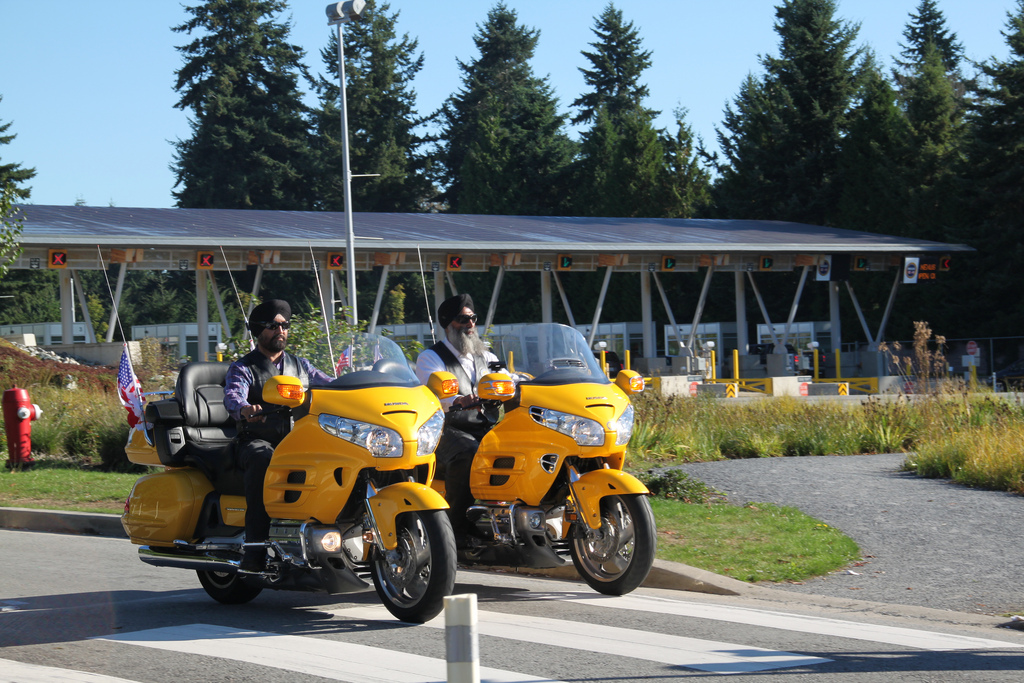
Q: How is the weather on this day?
A: It is clear.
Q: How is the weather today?
A: It is clear.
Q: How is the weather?
A: It is clear.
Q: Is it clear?
A: Yes, it is clear.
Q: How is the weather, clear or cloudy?
A: It is clear.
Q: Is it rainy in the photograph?
A: No, it is clear.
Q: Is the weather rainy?
A: No, it is clear.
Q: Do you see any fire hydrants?
A: Yes, there is a fire hydrant.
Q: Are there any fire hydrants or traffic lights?
A: Yes, there is a fire hydrant.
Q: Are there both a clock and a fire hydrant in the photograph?
A: No, there is a fire hydrant but no clocks.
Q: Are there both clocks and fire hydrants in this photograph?
A: No, there is a fire hydrant but no clocks.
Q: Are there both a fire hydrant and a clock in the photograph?
A: No, there is a fire hydrant but no clocks.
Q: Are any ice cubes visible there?
A: No, there are no ice cubes.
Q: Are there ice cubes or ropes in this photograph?
A: No, there are no ice cubes or ropes.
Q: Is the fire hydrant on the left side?
A: Yes, the fire hydrant is on the left of the image.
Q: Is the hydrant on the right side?
A: No, the hydrant is on the left of the image.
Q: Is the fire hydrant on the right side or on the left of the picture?
A: The fire hydrant is on the left of the image.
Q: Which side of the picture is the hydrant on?
A: The hydrant is on the left of the image.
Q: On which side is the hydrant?
A: The hydrant is on the left of the image.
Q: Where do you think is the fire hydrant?
A: The fire hydrant is on the grass.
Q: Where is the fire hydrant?
A: The fire hydrant is on the grass.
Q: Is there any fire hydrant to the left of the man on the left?
A: Yes, there is a fire hydrant to the left of the man.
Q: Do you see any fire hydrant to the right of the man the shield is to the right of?
A: No, the fire hydrant is to the left of the man.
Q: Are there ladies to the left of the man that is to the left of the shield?
A: No, there is a fire hydrant to the left of the man.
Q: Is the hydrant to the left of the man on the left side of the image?
A: Yes, the hydrant is to the left of the man.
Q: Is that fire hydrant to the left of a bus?
A: No, the fire hydrant is to the left of the man.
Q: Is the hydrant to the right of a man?
A: No, the hydrant is to the left of a man.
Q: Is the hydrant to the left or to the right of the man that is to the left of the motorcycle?
A: The hydrant is to the left of the man.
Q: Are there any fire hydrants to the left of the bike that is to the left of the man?
A: Yes, there is a fire hydrant to the left of the bike.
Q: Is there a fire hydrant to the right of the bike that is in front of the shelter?
A: No, the fire hydrant is to the left of the bike.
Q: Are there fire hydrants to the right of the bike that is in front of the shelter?
A: No, the fire hydrant is to the left of the bike.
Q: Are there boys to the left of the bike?
A: No, there is a fire hydrant to the left of the bike.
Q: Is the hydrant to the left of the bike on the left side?
A: Yes, the hydrant is to the left of the bike.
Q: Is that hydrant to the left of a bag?
A: No, the hydrant is to the left of the bike.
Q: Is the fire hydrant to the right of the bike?
A: No, the fire hydrant is to the left of the bike.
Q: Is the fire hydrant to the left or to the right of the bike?
A: The fire hydrant is to the left of the bike.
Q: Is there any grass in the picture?
A: Yes, there is grass.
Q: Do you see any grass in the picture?
A: Yes, there is grass.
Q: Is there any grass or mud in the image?
A: Yes, there is grass.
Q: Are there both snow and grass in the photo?
A: No, there is grass but no snow.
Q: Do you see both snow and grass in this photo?
A: No, there is grass but no snow.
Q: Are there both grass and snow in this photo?
A: No, there is grass but no snow.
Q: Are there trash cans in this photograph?
A: No, there are no trash cans.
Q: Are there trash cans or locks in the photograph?
A: No, there are no trash cans or locks.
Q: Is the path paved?
A: Yes, the path is paved.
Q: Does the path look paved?
A: Yes, the path is paved.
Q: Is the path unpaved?
A: No, the path is paved.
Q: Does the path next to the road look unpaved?
A: No, the path is paved.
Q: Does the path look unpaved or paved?
A: The path is paved.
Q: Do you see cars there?
A: No, there are no cars.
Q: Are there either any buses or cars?
A: No, there are no cars or buses.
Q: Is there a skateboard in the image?
A: No, there are no skateboards.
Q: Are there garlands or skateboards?
A: No, there are no skateboards or garlands.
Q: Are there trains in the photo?
A: No, there are no trains.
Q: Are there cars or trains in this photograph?
A: No, there are no trains or cars.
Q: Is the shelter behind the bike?
A: Yes, the shelter is behind the bike.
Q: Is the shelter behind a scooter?
A: No, the shelter is behind the bike.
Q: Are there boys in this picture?
A: No, there are no boys.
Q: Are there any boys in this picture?
A: No, there are no boys.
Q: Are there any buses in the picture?
A: No, there are no buses.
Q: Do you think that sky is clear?
A: Yes, the sky is clear.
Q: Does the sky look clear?
A: Yes, the sky is clear.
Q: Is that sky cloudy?
A: No, the sky is clear.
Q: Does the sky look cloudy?
A: No, the sky is clear.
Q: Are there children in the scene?
A: No, there are no children.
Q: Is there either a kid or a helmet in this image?
A: No, there are no children or helmets.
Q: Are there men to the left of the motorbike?
A: Yes, there is a man to the left of the motorbike.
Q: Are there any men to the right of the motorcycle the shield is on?
A: No, the man is to the left of the motorcycle.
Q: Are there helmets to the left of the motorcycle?
A: No, there is a man to the left of the motorcycle.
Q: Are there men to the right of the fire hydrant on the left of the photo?
A: Yes, there is a man to the right of the hydrant.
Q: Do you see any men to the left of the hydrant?
A: No, the man is to the right of the hydrant.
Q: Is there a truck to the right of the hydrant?
A: No, there is a man to the right of the hydrant.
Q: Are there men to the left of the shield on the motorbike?
A: Yes, there is a man to the left of the shield.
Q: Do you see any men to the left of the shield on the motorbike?
A: Yes, there is a man to the left of the shield.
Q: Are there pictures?
A: No, there are no pictures.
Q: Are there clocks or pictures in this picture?
A: No, there are no pictures or clocks.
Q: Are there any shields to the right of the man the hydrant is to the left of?
A: Yes, there is a shield to the right of the man.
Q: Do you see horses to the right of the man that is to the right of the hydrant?
A: No, there is a shield to the right of the man.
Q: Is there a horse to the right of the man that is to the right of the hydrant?
A: No, there is a shield to the right of the man.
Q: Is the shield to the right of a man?
A: Yes, the shield is to the right of a man.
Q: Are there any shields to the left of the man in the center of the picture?
A: Yes, there is a shield to the left of the man.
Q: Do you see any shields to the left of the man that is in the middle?
A: Yes, there is a shield to the left of the man.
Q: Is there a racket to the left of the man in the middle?
A: No, there is a shield to the left of the man.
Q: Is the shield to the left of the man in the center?
A: Yes, the shield is to the left of the man.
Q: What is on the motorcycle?
A: The shield is on the motorcycle.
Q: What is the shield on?
A: The shield is on the motorbike.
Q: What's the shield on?
A: The shield is on the motorbike.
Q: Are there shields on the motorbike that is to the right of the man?
A: Yes, there is a shield on the motorcycle.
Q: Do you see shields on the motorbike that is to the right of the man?
A: Yes, there is a shield on the motorcycle.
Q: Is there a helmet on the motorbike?
A: No, there is a shield on the motorbike.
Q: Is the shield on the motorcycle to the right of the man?
A: Yes, the shield is on the motorcycle.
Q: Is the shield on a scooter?
A: No, the shield is on the motorcycle.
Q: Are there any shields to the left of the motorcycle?
A: Yes, there is a shield to the left of the motorcycle.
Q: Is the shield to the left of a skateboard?
A: No, the shield is to the left of the motorcycle.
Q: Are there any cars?
A: No, there are no cars.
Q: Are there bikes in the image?
A: Yes, there is a bike.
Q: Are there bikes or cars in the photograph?
A: Yes, there is a bike.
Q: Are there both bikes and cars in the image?
A: No, there is a bike but no cars.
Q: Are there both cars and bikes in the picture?
A: No, there is a bike but no cars.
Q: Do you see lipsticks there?
A: No, there are no lipsticks.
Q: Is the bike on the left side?
A: Yes, the bike is on the left of the image.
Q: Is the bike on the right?
A: No, the bike is on the left of the image.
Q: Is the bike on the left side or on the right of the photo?
A: The bike is on the left of the image.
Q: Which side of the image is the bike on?
A: The bike is on the left of the image.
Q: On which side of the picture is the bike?
A: The bike is on the left of the image.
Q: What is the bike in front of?
A: The bike is in front of the shelter.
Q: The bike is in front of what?
A: The bike is in front of the shelter.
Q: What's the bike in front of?
A: The bike is in front of the shelter.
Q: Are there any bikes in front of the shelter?
A: Yes, there is a bike in front of the shelter.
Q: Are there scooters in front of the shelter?
A: No, there is a bike in front of the shelter.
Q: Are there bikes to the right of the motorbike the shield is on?
A: No, the bike is to the left of the motorbike.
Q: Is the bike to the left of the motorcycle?
A: Yes, the bike is to the left of the motorcycle.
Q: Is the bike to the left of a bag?
A: No, the bike is to the left of the motorcycle.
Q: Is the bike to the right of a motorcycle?
A: No, the bike is to the left of a motorcycle.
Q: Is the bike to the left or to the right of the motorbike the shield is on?
A: The bike is to the left of the motorbike.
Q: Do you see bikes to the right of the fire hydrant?
A: Yes, there is a bike to the right of the fire hydrant.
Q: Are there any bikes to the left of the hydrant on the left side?
A: No, the bike is to the right of the hydrant.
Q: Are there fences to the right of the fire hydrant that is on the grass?
A: No, there is a bike to the right of the fire hydrant.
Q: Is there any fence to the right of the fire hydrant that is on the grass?
A: No, there is a bike to the right of the fire hydrant.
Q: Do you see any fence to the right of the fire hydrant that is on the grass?
A: No, there is a bike to the right of the fire hydrant.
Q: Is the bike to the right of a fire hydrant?
A: Yes, the bike is to the right of a fire hydrant.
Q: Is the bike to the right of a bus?
A: No, the bike is to the right of a fire hydrant.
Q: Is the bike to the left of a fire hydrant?
A: No, the bike is to the right of a fire hydrant.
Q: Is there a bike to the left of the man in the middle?
A: Yes, there is a bike to the left of the man.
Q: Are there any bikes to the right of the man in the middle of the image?
A: No, the bike is to the left of the man.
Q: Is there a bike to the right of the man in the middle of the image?
A: No, the bike is to the left of the man.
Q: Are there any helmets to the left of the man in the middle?
A: No, there is a bike to the left of the man.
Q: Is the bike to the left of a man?
A: Yes, the bike is to the left of a man.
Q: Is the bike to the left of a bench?
A: No, the bike is to the left of a man.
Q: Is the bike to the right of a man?
A: No, the bike is to the left of a man.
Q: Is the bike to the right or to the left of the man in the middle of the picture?
A: The bike is to the left of the man.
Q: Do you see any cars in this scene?
A: No, there are no cars.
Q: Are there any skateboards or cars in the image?
A: No, there are no cars or skateboards.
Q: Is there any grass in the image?
A: Yes, there is grass.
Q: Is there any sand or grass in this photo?
A: Yes, there is grass.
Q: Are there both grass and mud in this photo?
A: No, there is grass but no mud.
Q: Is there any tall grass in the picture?
A: Yes, there is tall grass.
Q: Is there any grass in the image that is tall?
A: Yes, there is grass that is tall.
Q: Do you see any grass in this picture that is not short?
A: Yes, there is tall grass.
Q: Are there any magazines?
A: No, there are no magazines.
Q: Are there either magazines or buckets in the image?
A: No, there are no magazines or buckets.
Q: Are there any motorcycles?
A: Yes, there is a motorcycle.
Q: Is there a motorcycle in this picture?
A: Yes, there is a motorcycle.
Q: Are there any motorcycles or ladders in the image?
A: Yes, there is a motorcycle.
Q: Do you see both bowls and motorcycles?
A: No, there is a motorcycle but no bowls.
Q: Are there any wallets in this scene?
A: No, there are no wallets.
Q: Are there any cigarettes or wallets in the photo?
A: No, there are no wallets or cigarettes.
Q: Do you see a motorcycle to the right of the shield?
A: Yes, there is a motorcycle to the right of the shield.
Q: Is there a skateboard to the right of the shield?
A: No, there is a motorcycle to the right of the shield.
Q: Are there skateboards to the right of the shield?
A: No, there is a motorcycle to the right of the shield.